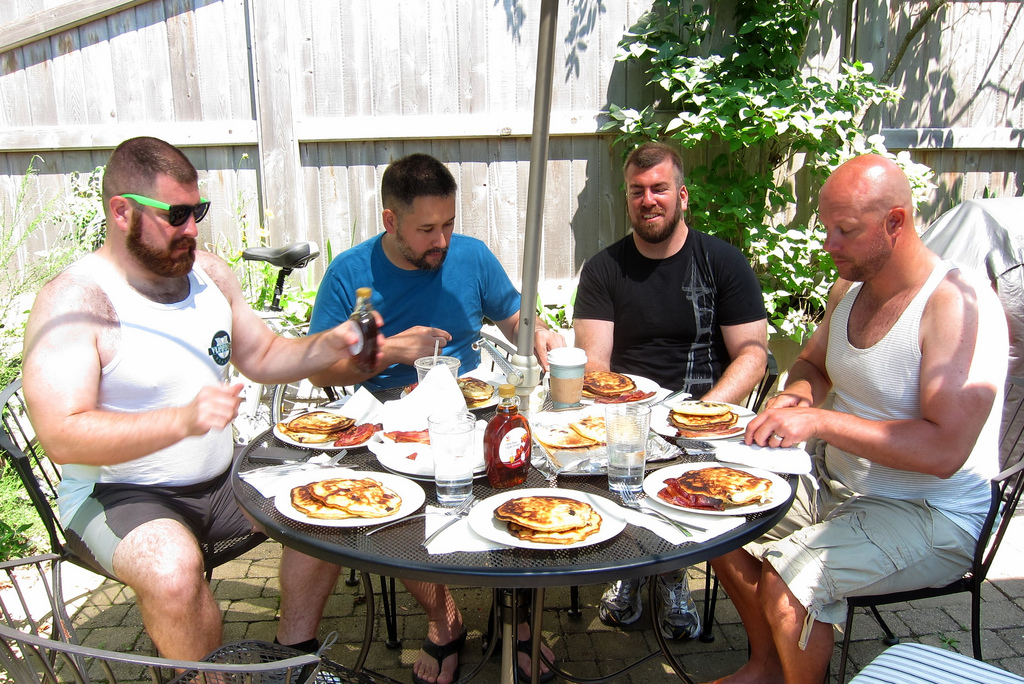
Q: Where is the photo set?
A: At the patio table.